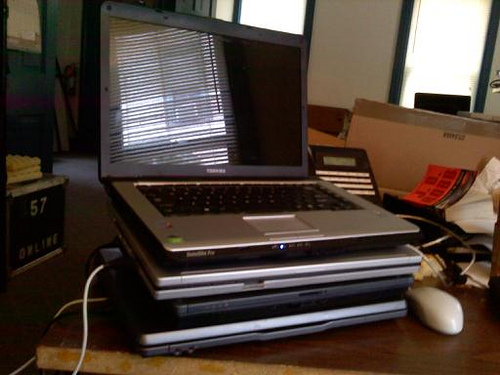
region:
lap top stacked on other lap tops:
[71, 3, 418, 360]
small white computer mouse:
[405, 280, 470, 337]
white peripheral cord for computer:
[46, 246, 123, 373]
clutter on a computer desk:
[377, 130, 492, 284]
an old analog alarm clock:
[10, 174, 75, 284]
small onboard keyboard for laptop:
[135, 175, 352, 215]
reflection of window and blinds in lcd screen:
[105, 20, 302, 170]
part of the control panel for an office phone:
[310, 142, 377, 199]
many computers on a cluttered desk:
[3, 5, 488, 355]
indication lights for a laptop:
[266, 238, 316, 254]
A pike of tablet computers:
[93, 1, 425, 351]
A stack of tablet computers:
[143, 256, 418, 336]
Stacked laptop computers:
[89, 0, 426, 359]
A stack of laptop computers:
[89, 1, 427, 353]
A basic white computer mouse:
[413, 281, 465, 338]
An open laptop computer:
[99, 8, 420, 263]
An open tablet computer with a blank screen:
[99, 8, 419, 260]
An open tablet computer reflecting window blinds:
[98, 3, 420, 253]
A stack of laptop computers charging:
[73, 236, 450, 353]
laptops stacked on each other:
[92, 0, 424, 359]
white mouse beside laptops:
[404, 282, 466, 337]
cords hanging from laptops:
[12, 252, 107, 374]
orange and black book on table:
[399, 160, 496, 215]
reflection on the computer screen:
[107, 14, 235, 165]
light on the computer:
[279, 242, 289, 254]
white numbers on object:
[22, 193, 52, 224]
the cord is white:
[76, 254, 109, 373]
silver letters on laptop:
[203, 162, 233, 179]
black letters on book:
[409, 164, 460, 207]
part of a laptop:
[403, 290, 413, 304]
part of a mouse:
[412, 317, 424, 318]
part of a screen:
[220, 150, 242, 183]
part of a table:
[321, 355, 327, 370]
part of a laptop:
[366, 155, 373, 170]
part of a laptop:
[388, 325, 398, 356]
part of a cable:
[123, 293, 141, 310]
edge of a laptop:
[256, 340, 261, 350]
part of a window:
[379, 75, 389, 100]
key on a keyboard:
[145, 183, 165, 193]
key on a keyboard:
[162, 196, 182, 204]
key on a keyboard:
[175, 199, 196, 221]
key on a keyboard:
[199, 192, 214, 209]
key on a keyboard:
[220, 199, 231, 213]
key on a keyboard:
[232, 193, 247, 213]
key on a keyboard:
[252, 201, 270, 209]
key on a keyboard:
[273, 198, 288, 210]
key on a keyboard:
[292, 193, 306, 211]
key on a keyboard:
[323, 192, 334, 210]